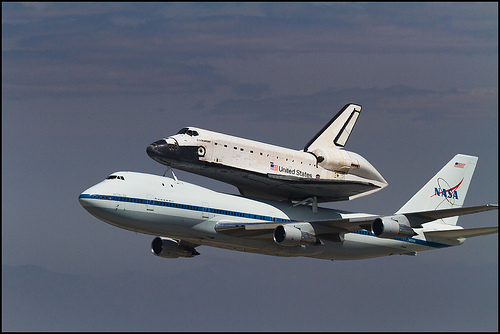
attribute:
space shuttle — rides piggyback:
[147, 99, 395, 207]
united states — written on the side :
[276, 163, 316, 179]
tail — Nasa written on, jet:
[391, 152, 482, 233]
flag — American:
[454, 160, 466, 168]